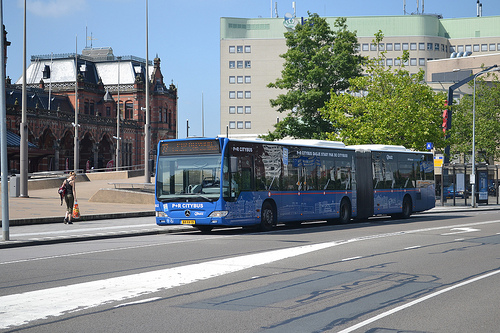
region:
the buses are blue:
[146, 130, 438, 230]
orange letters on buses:
[176, 139, 218, 154]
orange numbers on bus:
[153, 137, 169, 154]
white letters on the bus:
[171, 202, 208, 216]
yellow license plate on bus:
[176, 219, 198, 229]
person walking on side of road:
[56, 169, 86, 231]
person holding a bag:
[56, 169, 83, 226]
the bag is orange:
[70, 199, 86, 221]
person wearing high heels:
[58, 174, 83, 224]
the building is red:
[7, 74, 179, 172]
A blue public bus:
[146, 122, 457, 245]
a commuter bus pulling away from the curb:
[154, 129, 439, 235]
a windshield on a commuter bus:
[156, 142, 226, 200]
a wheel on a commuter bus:
[260, 200, 277, 231]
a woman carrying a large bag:
[59, 168, 82, 226]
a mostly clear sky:
[6, 0, 498, 137]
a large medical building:
[221, 14, 498, 151]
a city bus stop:
[450, 161, 490, 203]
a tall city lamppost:
[469, 63, 499, 211]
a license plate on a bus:
[180, 220, 197, 225]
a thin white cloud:
[21, 0, 81, 14]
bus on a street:
[140, 136, 455, 256]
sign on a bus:
[150, 130, 217, 160]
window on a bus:
[153, 155, 228, 203]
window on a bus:
[260, 147, 341, 188]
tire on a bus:
[251, 195, 293, 227]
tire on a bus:
[325, 180, 356, 231]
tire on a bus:
[391, 193, 417, 213]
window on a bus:
[376, 155, 432, 190]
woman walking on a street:
[52, 168, 82, 228]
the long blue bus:
[154, 137, 435, 232]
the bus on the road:
[155, 137, 435, 230]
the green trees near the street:
[257, 10, 499, 164]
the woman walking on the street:
[57, 171, 80, 224]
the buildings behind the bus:
[0, 0, 498, 181]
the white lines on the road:
[0, 219, 499, 331]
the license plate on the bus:
[180, 219, 195, 224]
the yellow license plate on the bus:
[180, 219, 195, 224]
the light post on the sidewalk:
[470, 66, 498, 206]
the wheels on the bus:
[192, 194, 412, 232]